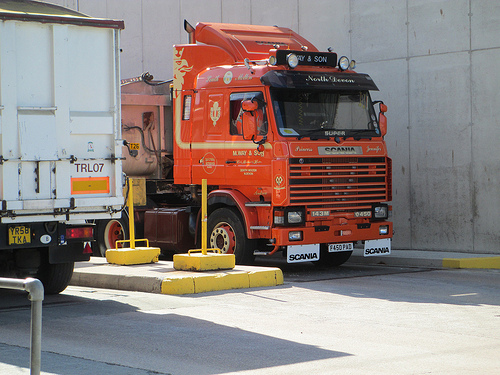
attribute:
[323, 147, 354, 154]
word — SCANIA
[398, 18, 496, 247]
wall — big, concrete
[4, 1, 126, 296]
truck — white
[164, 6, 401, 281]
big truck — orange